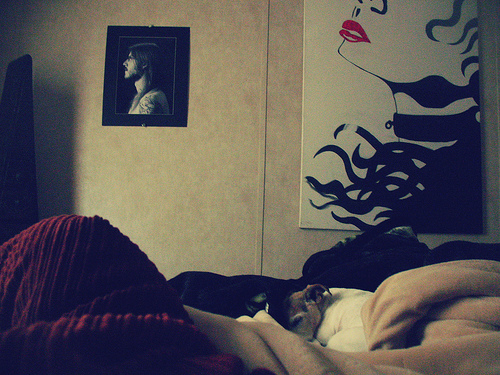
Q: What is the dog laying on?
A: The bed.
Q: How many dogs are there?
A: One.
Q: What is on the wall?
A: A picture.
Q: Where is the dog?
A: On top of the bed.